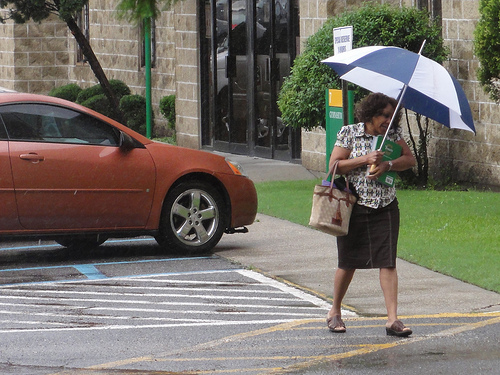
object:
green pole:
[141, 8, 161, 145]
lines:
[2, 262, 359, 333]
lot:
[3, 208, 497, 368]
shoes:
[323, 311, 412, 337]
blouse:
[335, 139, 401, 235]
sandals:
[316, 308, 413, 333]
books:
[370, 137, 405, 161]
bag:
[308, 180, 355, 234]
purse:
[306, 159, 358, 237]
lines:
[81, 308, 496, 372]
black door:
[204, 1, 299, 158]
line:
[76, 262, 109, 279]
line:
[0, 250, 210, 272]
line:
[103, 237, 156, 244]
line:
[0, 242, 63, 254]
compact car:
[4, 83, 263, 263]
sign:
[325, 89, 352, 176]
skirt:
[337, 192, 410, 269]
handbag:
[308, 160, 356, 235]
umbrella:
[313, 37, 478, 143]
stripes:
[376, 41, 451, 107]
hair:
[358, 92, 402, 125]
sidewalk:
[267, 212, 325, 314]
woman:
[327, 93, 415, 334]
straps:
[328, 161, 350, 194]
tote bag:
[306, 162, 354, 230]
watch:
[384, 160, 399, 170]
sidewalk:
[308, 273, 466, 373]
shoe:
[328, 313, 348, 331]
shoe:
[388, 318, 412, 337]